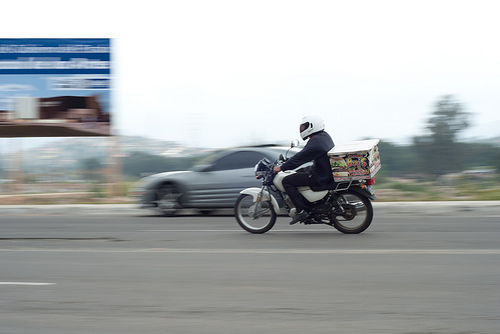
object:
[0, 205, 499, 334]
street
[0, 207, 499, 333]
traveling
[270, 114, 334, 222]
person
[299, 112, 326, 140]
helmet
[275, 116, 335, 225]
biker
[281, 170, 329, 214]
pants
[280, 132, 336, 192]
jacket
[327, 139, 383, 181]
basket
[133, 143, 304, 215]
vehicle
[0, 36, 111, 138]
billboard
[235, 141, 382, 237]
motorcycle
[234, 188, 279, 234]
wheel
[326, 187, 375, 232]
wheel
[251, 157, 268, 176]
headlight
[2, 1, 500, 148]
sky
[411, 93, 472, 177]
tree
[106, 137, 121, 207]
post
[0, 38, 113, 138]
sign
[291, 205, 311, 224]
shoes